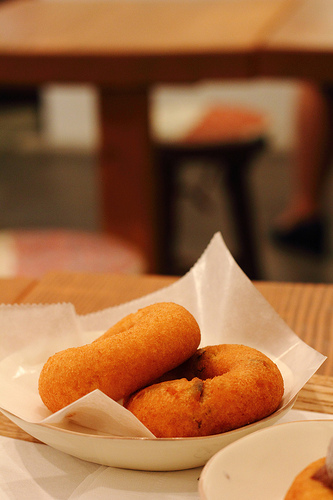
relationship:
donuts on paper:
[55, 309, 264, 441] [45, 238, 294, 451]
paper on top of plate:
[45, 238, 294, 451] [14, 402, 313, 474]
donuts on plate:
[55, 309, 264, 441] [0, 329, 300, 472]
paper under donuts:
[45, 238, 294, 451] [55, 309, 264, 441]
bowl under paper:
[14, 402, 313, 474] [45, 238, 294, 451]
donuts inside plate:
[55, 309, 264, 441] [0, 329, 300, 472]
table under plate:
[37, 264, 330, 354] [14, 402, 313, 474]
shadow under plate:
[23, 439, 208, 496] [14, 402, 313, 474]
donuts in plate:
[55, 309, 264, 441] [0, 329, 300, 472]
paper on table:
[8, 437, 191, 499] [37, 264, 330, 354]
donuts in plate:
[55, 309, 264, 441] [14, 402, 313, 474]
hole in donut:
[175, 354, 225, 391] [145, 345, 267, 430]